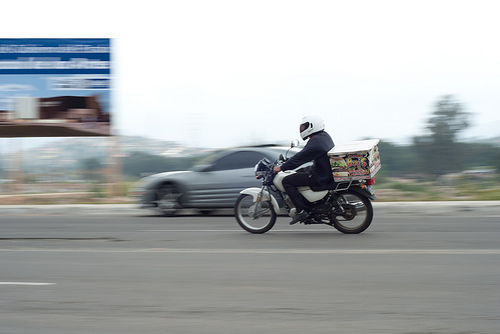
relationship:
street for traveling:
[0, 205, 499, 334] [0, 207, 499, 333]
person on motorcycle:
[270, 114, 334, 222] [235, 141, 382, 237]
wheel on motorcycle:
[234, 188, 279, 234] [235, 141, 382, 237]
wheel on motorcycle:
[326, 187, 375, 232] [235, 141, 382, 237]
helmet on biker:
[299, 112, 326, 140] [275, 116, 335, 225]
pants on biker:
[281, 170, 329, 214] [275, 116, 335, 225]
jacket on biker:
[280, 132, 336, 192] [275, 116, 335, 225]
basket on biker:
[326, 139, 383, 184] [275, 116, 335, 225]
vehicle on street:
[133, 143, 304, 215] [0, 205, 499, 334]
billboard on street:
[0, 36, 111, 138] [0, 205, 499, 334]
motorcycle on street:
[235, 141, 382, 237] [0, 205, 499, 334]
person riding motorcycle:
[270, 114, 334, 222] [235, 141, 382, 237]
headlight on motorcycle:
[251, 157, 268, 176] [235, 141, 382, 237]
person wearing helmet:
[270, 114, 334, 222] [299, 112, 326, 140]